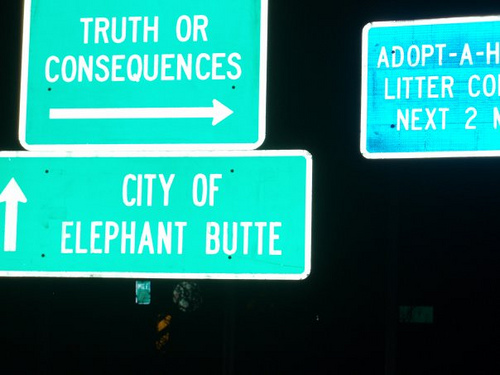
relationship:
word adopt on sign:
[376, 42, 446, 69] [359, 14, 497, 160]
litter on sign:
[381, 76, 456, 103] [343, 20, 495, 160]